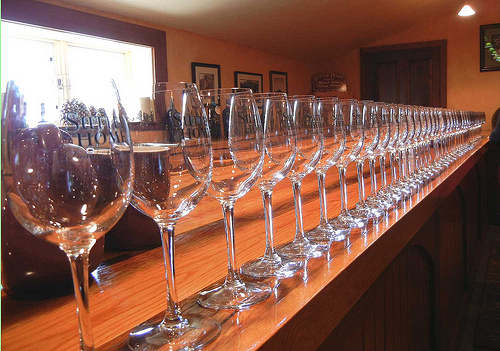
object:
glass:
[123, 82, 223, 350]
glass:
[180, 83, 276, 312]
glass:
[228, 88, 307, 282]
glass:
[306, 95, 350, 245]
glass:
[328, 94, 365, 234]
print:
[191, 60, 224, 110]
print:
[231, 67, 268, 109]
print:
[270, 69, 290, 100]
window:
[0, 16, 157, 127]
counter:
[0, 111, 490, 350]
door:
[357, 39, 448, 114]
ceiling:
[62, 0, 457, 66]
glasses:
[0, 72, 136, 351]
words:
[60, 104, 130, 153]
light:
[454, 5, 478, 18]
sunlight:
[0, 18, 166, 127]